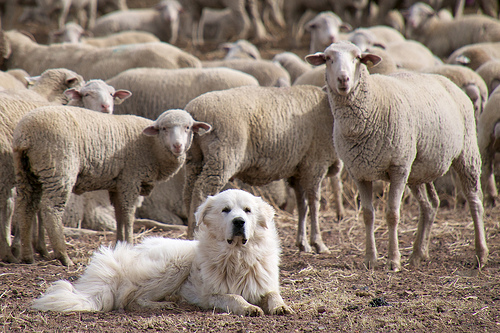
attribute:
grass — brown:
[309, 277, 490, 329]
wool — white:
[58, 117, 176, 182]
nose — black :
[229, 218, 247, 243]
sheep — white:
[202, 86, 329, 176]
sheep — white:
[14, 109, 191, 224]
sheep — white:
[69, 82, 123, 111]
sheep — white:
[112, 69, 255, 85]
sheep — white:
[299, 36, 496, 274]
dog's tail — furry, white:
[28, 239, 123, 311]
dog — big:
[54, 178, 374, 315]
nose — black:
[226, 203, 253, 233]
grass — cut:
[320, 289, 355, 309]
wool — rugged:
[318, 152, 343, 179]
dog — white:
[34, 187, 291, 318]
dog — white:
[43, 188, 313, 325]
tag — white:
[196, 126, 207, 138]